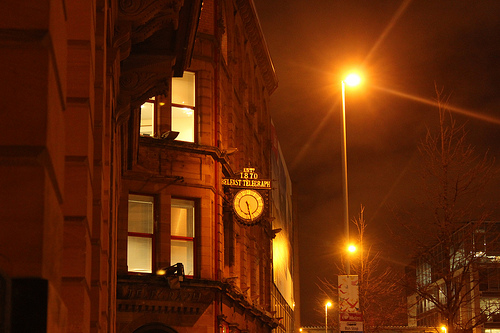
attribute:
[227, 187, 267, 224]
clock — white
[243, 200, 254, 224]
clock hands — black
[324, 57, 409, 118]
light — bright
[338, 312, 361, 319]
writing — large and white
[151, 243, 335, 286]
base light — gray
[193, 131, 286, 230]
clock face — large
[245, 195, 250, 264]
clock hands — large and metal